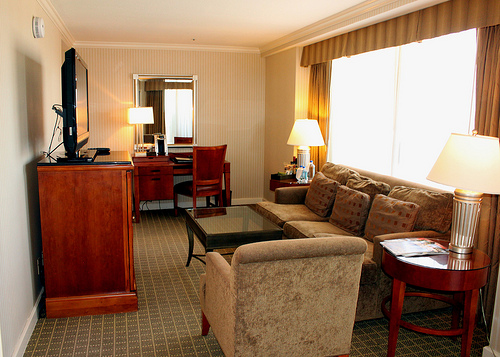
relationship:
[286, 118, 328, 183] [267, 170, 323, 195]
lamp on top of table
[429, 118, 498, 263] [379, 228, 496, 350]
lamp on top of wooden table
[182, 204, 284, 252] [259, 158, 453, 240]
coffee table in front of sofa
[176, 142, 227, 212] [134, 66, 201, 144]
chair in front of mirror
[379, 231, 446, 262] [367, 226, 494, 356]
magazine on top of table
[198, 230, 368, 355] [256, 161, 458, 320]
chair next to sofa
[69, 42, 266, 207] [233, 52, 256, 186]
wall has wallpaper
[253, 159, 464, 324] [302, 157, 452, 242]
couch has pillows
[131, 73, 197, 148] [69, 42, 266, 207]
mirror on wall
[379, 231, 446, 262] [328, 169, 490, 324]
magazine on table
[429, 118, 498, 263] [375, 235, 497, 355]
lamp on end table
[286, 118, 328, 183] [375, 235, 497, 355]
lamp on end table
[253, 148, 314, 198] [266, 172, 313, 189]
objects on end table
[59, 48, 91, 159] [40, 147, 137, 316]
tv on console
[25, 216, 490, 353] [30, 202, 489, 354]
carpet on floor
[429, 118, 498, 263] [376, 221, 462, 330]
lamp on table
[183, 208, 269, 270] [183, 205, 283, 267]
trim on table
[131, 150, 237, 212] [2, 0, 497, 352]
desk on side of room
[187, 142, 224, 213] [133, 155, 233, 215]
chair at desk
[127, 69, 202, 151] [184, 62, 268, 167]
mirror on wall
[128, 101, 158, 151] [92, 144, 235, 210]
lamp on table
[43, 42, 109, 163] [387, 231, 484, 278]
television on wooden table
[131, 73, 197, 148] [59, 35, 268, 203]
mirror hanging on wall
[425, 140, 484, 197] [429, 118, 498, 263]
shade on lamp